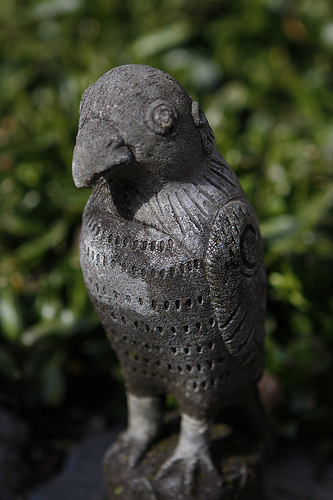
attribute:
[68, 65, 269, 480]
statue — stone, falcon, bird, black, tall, silver, grey, standing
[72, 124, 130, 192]
beak — stone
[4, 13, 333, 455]
leaves — green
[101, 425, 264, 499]
pedestool — round, small, black